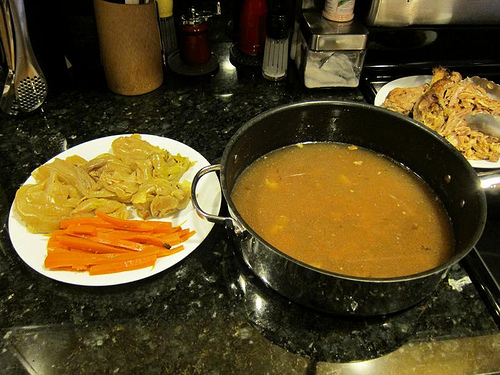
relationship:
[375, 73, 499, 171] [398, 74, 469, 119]
plate has chicken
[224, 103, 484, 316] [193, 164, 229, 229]
pot has handle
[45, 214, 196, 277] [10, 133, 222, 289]
carrots on a plate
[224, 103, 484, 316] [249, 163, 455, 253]
pot has broth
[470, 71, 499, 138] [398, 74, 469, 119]
tongs on chicken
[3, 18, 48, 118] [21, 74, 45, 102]
utensils has holes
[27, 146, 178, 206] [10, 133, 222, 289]
cabbage on a plate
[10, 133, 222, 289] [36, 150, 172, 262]
plate has food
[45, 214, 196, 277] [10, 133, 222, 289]
carrots on plate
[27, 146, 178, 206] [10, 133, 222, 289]
cabbage on plate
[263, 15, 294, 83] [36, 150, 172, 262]
shaker behind food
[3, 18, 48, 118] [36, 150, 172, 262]
utensils behind food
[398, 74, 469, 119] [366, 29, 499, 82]
chicken on stove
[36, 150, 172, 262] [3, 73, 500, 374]
food on counter top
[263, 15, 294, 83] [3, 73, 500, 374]
shaker on counter top